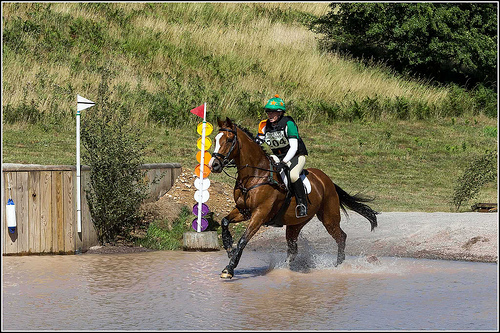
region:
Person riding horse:
[217, 85, 382, 280]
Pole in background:
[168, 87, 213, 234]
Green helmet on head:
[260, 85, 292, 117]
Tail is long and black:
[340, 175, 383, 234]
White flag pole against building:
[59, 83, 109, 240]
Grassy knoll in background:
[12, 17, 497, 141]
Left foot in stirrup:
[290, 202, 316, 234]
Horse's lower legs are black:
[213, 226, 261, 298]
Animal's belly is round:
[273, 202, 319, 234]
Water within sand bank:
[15, 253, 495, 331]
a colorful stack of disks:
[182, 105, 214, 225]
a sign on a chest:
[264, 132, 291, 150]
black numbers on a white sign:
[269, 140, 287, 144]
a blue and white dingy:
[1, 197, 28, 228]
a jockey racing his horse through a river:
[193, 88, 377, 275]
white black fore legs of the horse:
[220, 217, 243, 276]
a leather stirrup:
[291, 202, 308, 215]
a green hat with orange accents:
[262, 95, 287, 109]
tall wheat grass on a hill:
[263, 42, 325, 78]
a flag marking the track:
[67, 92, 89, 239]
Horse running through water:
[228, 201, 373, 296]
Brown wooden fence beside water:
[8, 155, 173, 266]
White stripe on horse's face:
[210, 128, 227, 167]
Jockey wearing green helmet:
[262, 95, 284, 124]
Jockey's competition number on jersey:
[261, 128, 291, 154]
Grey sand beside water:
[398, 216, 487, 263]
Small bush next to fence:
[88, 133, 161, 249]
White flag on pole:
[68, 95, 104, 240]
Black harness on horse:
[208, 125, 245, 172]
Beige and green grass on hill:
[141, 11, 359, 95]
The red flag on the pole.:
[186, 101, 208, 121]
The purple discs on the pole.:
[191, 207, 208, 233]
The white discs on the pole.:
[190, 180, 212, 207]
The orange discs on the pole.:
[190, 150, 210, 171]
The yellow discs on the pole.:
[196, 120, 211, 150]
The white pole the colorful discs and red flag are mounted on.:
[198, 97, 208, 235]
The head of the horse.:
[197, 117, 240, 175]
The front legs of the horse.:
[204, 202, 259, 287]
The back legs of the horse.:
[284, 203, 347, 281]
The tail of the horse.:
[338, 177, 384, 229]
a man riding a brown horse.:
[197, 79, 386, 291]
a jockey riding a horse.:
[248, 84, 316, 234]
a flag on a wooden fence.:
[53, 60, 125, 271]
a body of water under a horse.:
[3, 255, 498, 327]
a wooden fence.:
[0, 156, 214, 271]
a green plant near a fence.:
[57, 70, 156, 242]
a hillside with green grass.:
[0, 0, 497, 211]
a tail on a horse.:
[331, 182, 396, 226]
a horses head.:
[189, 94, 256, 172]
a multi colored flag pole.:
[171, 105, 218, 255]